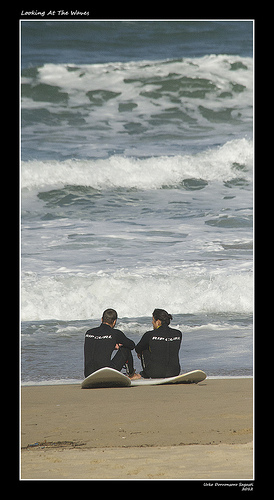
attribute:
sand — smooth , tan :
[37, 423, 112, 443]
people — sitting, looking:
[81, 309, 185, 381]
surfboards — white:
[84, 365, 205, 388]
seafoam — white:
[24, 58, 257, 323]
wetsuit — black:
[138, 326, 183, 378]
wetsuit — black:
[82, 323, 136, 381]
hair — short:
[100, 308, 118, 324]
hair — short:
[154, 306, 169, 327]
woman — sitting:
[137, 306, 184, 378]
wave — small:
[22, 315, 251, 339]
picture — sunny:
[18, 19, 254, 480]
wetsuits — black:
[81, 325, 186, 379]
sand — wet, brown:
[20, 321, 253, 448]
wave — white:
[22, 140, 253, 193]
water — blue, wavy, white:
[22, 23, 257, 336]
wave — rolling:
[22, 53, 253, 117]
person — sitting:
[84, 306, 137, 383]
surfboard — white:
[81, 367, 132, 391]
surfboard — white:
[136, 369, 209, 385]